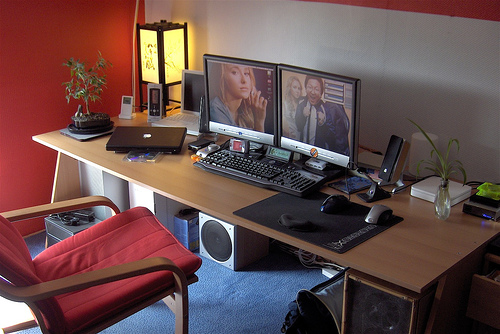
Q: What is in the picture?
A: Desk.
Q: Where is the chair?
A: Front of the desk.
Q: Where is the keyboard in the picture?
A: On the desk.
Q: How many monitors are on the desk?
A: Two.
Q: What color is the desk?
A: Brown.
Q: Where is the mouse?
A: On the mouse pad.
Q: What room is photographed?
A: An Office.